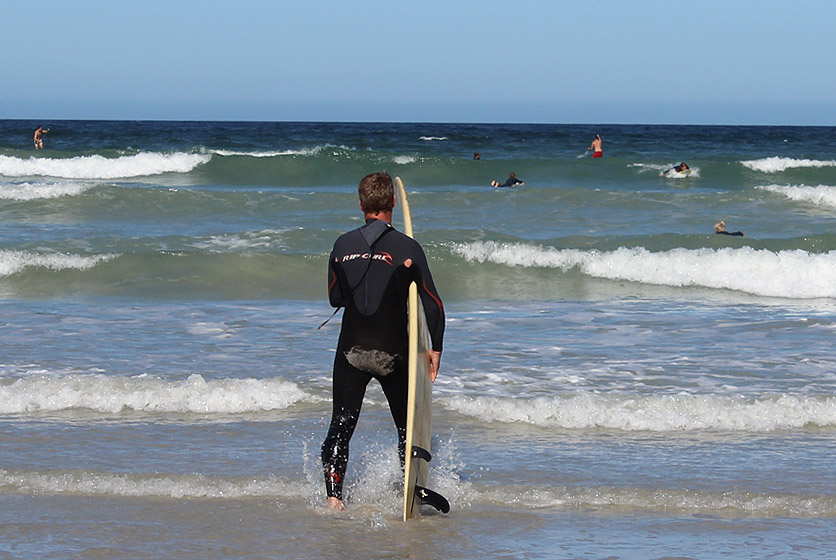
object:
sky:
[0, 1, 835, 125]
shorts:
[593, 150, 603, 158]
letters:
[334, 251, 392, 265]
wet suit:
[320, 218, 445, 512]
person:
[489, 172, 525, 188]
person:
[659, 161, 690, 178]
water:
[1, 124, 836, 560]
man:
[315, 171, 445, 513]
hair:
[358, 169, 395, 216]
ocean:
[0, 118, 836, 560]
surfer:
[33, 126, 50, 150]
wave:
[0, 139, 445, 202]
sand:
[342, 345, 397, 376]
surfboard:
[396, 176, 435, 522]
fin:
[412, 445, 433, 462]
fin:
[415, 485, 450, 514]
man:
[588, 134, 603, 158]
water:
[345, 427, 474, 521]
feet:
[327, 497, 348, 513]